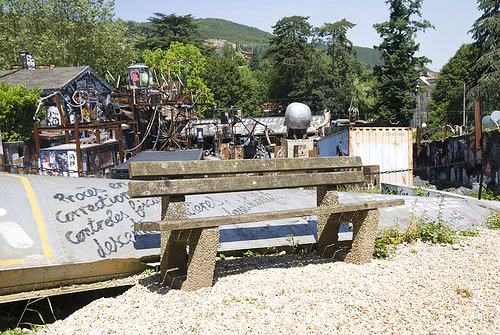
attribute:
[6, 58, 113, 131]
building — small, blue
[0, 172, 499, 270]
paint — gray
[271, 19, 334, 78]
tree — green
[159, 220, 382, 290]
legs — brown, cement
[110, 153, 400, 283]
bench — empty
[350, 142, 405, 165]
paint — grey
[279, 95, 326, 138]
ball — color silver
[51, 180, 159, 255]
writing — blue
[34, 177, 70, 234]
paint — gray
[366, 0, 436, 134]
tree — color brown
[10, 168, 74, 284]
line — yellow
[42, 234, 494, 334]
pebbles — brown, white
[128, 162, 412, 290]
bench — wooden, grey, brown, cement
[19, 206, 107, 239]
wall — gray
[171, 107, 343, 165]
building — various different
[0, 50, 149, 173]
building — various different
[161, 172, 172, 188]
bolts — black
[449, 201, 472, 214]
paint — gray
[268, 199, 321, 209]
paint — gray